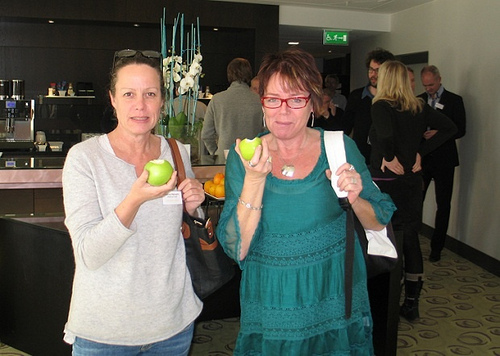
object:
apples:
[142, 159, 174, 186]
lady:
[61, 48, 220, 355]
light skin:
[107, 62, 164, 178]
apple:
[238, 137, 264, 161]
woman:
[216, 46, 401, 355]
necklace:
[270, 127, 308, 177]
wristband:
[238, 196, 264, 211]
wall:
[274, 0, 499, 272]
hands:
[381, 155, 406, 174]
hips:
[405, 165, 423, 182]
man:
[199, 53, 266, 165]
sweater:
[200, 81, 264, 164]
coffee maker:
[37, 81, 97, 139]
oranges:
[213, 172, 226, 184]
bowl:
[203, 188, 226, 201]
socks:
[406, 272, 426, 281]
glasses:
[260, 90, 311, 110]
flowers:
[179, 76, 194, 88]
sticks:
[159, 7, 167, 54]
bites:
[149, 158, 164, 165]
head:
[257, 50, 325, 140]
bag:
[166, 135, 240, 297]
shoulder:
[150, 133, 187, 150]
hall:
[277, 22, 391, 100]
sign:
[323, 29, 350, 46]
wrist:
[242, 181, 266, 191]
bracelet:
[238, 197, 264, 211]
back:
[376, 100, 420, 170]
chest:
[139, 177, 189, 221]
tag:
[163, 191, 183, 205]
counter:
[0, 166, 64, 192]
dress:
[216, 131, 400, 356]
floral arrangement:
[156, 7, 202, 164]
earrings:
[308, 110, 315, 129]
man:
[341, 46, 398, 167]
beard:
[369, 77, 378, 89]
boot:
[400, 276, 427, 324]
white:
[103, 164, 115, 182]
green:
[276, 200, 298, 222]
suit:
[369, 98, 422, 178]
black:
[450, 104, 457, 114]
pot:
[155, 117, 203, 163]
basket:
[203, 205, 226, 226]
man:
[411, 59, 466, 264]